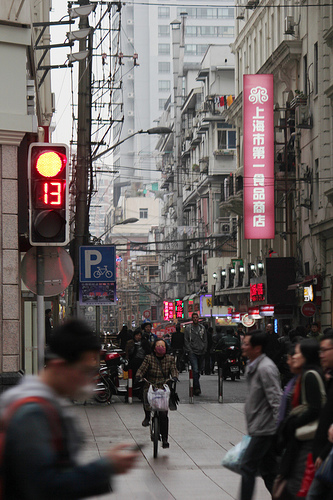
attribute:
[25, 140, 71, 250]
light — pedestrian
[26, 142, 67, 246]
street light — cross walk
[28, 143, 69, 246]
traffic-light — red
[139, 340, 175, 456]
man — biking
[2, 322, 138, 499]
guy — walking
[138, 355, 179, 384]
jacket — plaid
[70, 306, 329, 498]
street — crowded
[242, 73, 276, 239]
sign — red, white, asian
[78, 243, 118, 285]
sign — blue, informative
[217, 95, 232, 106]
clothes — drying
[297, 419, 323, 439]
purse — white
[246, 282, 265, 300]
sign — neon